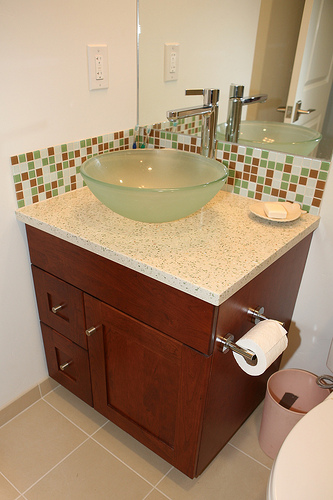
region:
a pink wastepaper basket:
[251, 367, 329, 454]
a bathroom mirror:
[128, 0, 322, 153]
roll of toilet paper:
[238, 319, 285, 377]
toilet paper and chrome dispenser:
[218, 297, 284, 379]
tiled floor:
[0, 392, 123, 493]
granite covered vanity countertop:
[49, 178, 221, 301]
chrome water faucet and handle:
[164, 84, 216, 158]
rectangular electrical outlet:
[85, 40, 109, 93]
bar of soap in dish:
[249, 193, 301, 218]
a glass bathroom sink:
[82, 141, 230, 219]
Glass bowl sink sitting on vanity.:
[77, 145, 233, 228]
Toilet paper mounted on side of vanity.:
[225, 315, 296, 379]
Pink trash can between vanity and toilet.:
[253, 357, 331, 467]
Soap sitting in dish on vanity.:
[248, 195, 306, 225]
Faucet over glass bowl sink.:
[165, 84, 232, 168]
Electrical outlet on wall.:
[81, 38, 117, 93]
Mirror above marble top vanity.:
[129, 2, 331, 164]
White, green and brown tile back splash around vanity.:
[11, 151, 72, 206]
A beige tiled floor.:
[16, 396, 120, 499]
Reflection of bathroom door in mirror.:
[276, 3, 326, 136]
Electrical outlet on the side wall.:
[86, 44, 111, 93]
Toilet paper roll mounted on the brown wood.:
[222, 313, 300, 363]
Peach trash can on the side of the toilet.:
[261, 347, 332, 480]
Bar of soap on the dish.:
[263, 202, 289, 221]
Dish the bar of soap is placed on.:
[249, 199, 301, 224]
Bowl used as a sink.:
[79, 141, 232, 228]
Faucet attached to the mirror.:
[163, 71, 228, 159]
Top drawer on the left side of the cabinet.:
[31, 276, 82, 346]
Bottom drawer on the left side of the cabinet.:
[40, 334, 88, 403]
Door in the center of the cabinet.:
[83, 318, 213, 477]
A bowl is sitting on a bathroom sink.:
[72, 143, 233, 224]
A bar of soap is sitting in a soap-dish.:
[241, 195, 304, 226]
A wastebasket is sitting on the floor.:
[256, 363, 331, 463]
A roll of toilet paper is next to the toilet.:
[226, 312, 291, 380]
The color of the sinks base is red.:
[21, 215, 315, 480]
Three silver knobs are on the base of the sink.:
[41, 296, 99, 376]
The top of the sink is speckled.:
[13, 166, 321, 309]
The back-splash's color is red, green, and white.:
[8, 123, 331, 224]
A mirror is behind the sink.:
[136, 0, 331, 164]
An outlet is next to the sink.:
[79, 40, 114, 96]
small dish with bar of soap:
[249, 189, 298, 226]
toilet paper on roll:
[233, 317, 291, 379]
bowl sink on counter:
[84, 137, 211, 232]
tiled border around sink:
[13, 161, 80, 203]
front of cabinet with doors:
[31, 267, 188, 413]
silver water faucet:
[165, 87, 213, 155]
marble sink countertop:
[171, 242, 218, 285]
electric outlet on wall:
[76, 41, 117, 96]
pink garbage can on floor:
[262, 374, 300, 460]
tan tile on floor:
[28, 421, 91, 477]